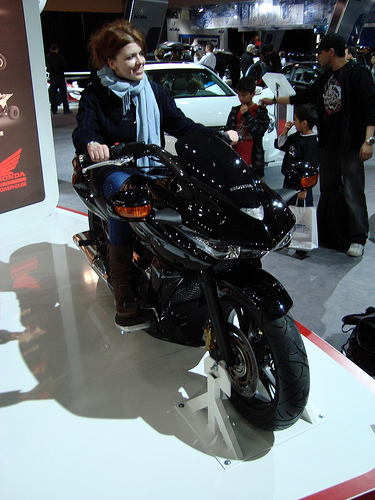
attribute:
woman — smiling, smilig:
[64, 33, 167, 148]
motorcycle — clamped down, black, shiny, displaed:
[99, 130, 305, 312]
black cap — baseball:
[315, 30, 353, 62]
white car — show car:
[156, 58, 238, 121]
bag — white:
[226, 127, 254, 139]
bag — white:
[286, 199, 315, 244]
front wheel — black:
[213, 282, 311, 438]